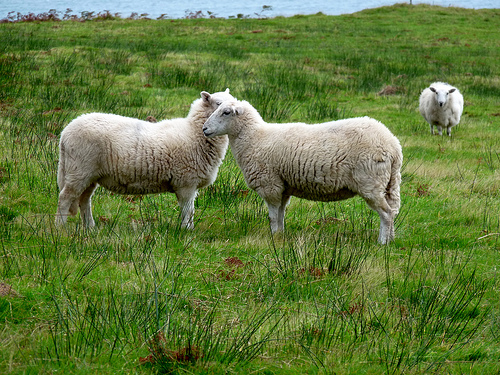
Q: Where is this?
A: This is at the field.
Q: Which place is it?
A: It is a field.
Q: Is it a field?
A: Yes, it is a field.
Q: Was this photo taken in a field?
A: Yes, it was taken in a field.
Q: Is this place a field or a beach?
A: It is a field.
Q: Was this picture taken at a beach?
A: No, the picture was taken in a field.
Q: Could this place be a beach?
A: No, it is a field.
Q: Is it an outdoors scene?
A: Yes, it is outdoors.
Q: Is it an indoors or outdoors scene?
A: It is outdoors.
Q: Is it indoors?
A: No, it is outdoors.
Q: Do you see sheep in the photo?
A: Yes, there is a sheep.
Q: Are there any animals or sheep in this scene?
A: Yes, there is a sheep.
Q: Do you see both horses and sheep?
A: No, there is a sheep but no horses.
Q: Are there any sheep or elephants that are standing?
A: Yes, the sheep is standing.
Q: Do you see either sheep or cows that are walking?
A: Yes, the sheep is walking.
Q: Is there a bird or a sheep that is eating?
A: Yes, the sheep is eating.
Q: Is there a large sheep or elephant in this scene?
A: Yes, there is a large sheep.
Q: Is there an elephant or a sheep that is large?
A: Yes, the sheep is large.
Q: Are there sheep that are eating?
A: Yes, there is a sheep that is eating.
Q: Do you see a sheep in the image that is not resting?
A: Yes, there is a sheep that is eating .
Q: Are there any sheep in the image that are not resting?
A: Yes, there is a sheep that is eating.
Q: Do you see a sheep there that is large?
A: Yes, there is a large sheep.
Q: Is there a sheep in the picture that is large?
A: Yes, there is a large sheep.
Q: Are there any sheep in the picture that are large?
A: Yes, there is a sheep that is large.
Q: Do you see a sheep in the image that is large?
A: Yes, there is a sheep that is large.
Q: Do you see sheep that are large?
A: Yes, there is a sheep that is large.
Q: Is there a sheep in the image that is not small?
A: Yes, there is a large sheep.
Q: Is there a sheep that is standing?
A: Yes, there is a sheep that is standing.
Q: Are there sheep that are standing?
A: Yes, there is a sheep that is standing.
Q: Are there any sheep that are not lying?
A: Yes, there is a sheep that is standing.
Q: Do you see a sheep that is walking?
A: Yes, there is a sheep that is walking.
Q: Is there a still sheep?
A: Yes, there is a still sheep.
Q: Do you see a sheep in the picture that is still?
A: Yes, there is a sheep that is still.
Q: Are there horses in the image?
A: No, there are no horses.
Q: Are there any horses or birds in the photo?
A: No, there are no horses or birds.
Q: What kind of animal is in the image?
A: The animal is a sheep.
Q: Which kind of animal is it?
A: The animal is a sheep.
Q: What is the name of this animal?
A: This is a sheep.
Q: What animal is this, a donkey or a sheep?
A: This is a sheep.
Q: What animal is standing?
A: The animal is a sheep.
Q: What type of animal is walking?
A: The animal is a sheep.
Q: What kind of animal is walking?
A: The animal is a sheep.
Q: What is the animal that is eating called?
A: The animal is a sheep.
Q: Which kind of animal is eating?
A: The animal is a sheep.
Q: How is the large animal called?
A: The animal is a sheep.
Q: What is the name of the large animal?
A: The animal is a sheep.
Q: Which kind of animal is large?
A: The animal is a sheep.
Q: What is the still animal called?
A: The animal is a sheep.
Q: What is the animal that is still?
A: The animal is a sheep.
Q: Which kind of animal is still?
A: The animal is a sheep.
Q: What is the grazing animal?
A: The animal is a sheep.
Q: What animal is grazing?
A: The animal is a sheep.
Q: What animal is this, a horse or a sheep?
A: This is a sheep.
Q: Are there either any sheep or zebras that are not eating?
A: No, there is a sheep but it is eating.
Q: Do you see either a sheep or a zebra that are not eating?
A: No, there is a sheep but it is eating.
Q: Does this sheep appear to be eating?
A: Yes, the sheep is eating.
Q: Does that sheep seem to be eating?
A: Yes, the sheep is eating.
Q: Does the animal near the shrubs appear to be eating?
A: Yes, the sheep is eating.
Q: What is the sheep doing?
A: The sheep is eating.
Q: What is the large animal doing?
A: The sheep is eating.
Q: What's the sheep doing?
A: The sheep is eating.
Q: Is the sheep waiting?
A: No, the sheep is eating.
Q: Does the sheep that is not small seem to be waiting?
A: No, the sheep is eating.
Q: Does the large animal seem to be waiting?
A: No, the sheep is eating.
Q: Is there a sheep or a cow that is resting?
A: No, there is a sheep but it is eating.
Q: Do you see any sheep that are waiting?
A: No, there is a sheep but it is eating.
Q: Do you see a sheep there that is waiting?
A: No, there is a sheep but it is eating.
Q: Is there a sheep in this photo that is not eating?
A: No, there is a sheep but it is eating.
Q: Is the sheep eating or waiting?
A: The sheep is eating.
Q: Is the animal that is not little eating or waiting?
A: The sheep is eating.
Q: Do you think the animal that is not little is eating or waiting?
A: The sheep is eating.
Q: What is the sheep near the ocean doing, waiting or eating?
A: The sheep is eating.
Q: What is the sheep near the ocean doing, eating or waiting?
A: The sheep is eating.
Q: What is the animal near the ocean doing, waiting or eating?
A: The sheep is eating.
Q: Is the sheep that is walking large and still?
A: Yes, the sheep is large and still.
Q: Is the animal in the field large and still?
A: Yes, the sheep is large and still.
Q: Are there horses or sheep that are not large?
A: No, there is a sheep but it is large.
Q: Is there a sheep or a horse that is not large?
A: No, there is a sheep but it is large.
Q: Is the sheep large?
A: Yes, the sheep is large.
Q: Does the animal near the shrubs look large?
A: Yes, the sheep is large.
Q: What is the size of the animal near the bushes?
A: The sheep is large.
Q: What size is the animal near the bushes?
A: The sheep is large.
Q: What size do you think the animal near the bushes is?
A: The sheep is large.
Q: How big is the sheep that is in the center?
A: The sheep is large.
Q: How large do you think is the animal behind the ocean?
A: The sheep is large.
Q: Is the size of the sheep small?
A: No, the sheep is large.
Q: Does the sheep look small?
A: No, the sheep is large.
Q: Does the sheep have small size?
A: No, the sheep is large.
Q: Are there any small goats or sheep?
A: No, there is a sheep but it is large.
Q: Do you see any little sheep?
A: No, there is a sheep but it is large.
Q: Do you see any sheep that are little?
A: No, there is a sheep but it is large.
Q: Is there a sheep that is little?
A: No, there is a sheep but it is large.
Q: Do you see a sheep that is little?
A: No, there is a sheep but it is large.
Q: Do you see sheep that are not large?
A: No, there is a sheep but it is large.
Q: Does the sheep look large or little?
A: The sheep is large.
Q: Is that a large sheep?
A: Yes, that is a large sheep.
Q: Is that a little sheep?
A: No, that is a large sheep.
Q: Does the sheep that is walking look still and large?
A: Yes, the sheep is still and large.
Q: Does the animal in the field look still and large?
A: Yes, the sheep is still and large.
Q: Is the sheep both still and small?
A: No, the sheep is still but large.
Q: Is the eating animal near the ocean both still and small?
A: No, the sheep is still but large.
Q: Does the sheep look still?
A: Yes, the sheep is still.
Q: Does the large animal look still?
A: Yes, the sheep is still.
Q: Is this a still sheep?
A: Yes, this is a still sheep.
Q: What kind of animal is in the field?
A: The animal is a sheep.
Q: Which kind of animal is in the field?
A: The animal is a sheep.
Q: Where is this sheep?
A: The sheep is in the field.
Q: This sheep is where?
A: The sheep is in the field.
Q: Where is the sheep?
A: The sheep is in the field.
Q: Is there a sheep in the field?
A: Yes, there is a sheep in the field.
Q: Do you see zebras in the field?
A: No, there is a sheep in the field.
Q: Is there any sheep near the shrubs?
A: Yes, there is a sheep near the shrubs.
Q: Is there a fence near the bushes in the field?
A: No, there is a sheep near the shrubs.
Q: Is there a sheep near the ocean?
A: Yes, there is a sheep near the ocean.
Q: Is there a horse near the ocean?
A: No, there is a sheep near the ocean.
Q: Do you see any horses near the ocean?
A: No, there is a sheep near the ocean.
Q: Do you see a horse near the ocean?
A: No, there is a sheep near the ocean.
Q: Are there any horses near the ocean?
A: No, there is a sheep near the ocean.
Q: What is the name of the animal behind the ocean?
A: The animal is a sheep.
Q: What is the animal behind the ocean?
A: The animal is a sheep.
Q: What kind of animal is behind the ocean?
A: The animal is a sheep.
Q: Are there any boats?
A: No, there are no boats.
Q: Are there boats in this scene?
A: No, there are no boats.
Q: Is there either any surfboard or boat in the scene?
A: No, there are no boats or surfboards.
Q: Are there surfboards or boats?
A: No, there are no boats or surfboards.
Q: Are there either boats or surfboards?
A: No, there are no boats or surfboards.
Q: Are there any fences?
A: No, there are no fences.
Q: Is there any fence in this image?
A: No, there are no fences.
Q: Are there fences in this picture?
A: No, there are no fences.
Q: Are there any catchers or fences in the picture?
A: No, there are no fences or catchers.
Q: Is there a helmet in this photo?
A: No, there are no helmets.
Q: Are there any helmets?
A: No, there are no helmets.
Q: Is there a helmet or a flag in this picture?
A: No, there are no helmets or flags.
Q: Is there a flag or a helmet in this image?
A: No, there are no helmets or flags.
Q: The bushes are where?
A: The bushes are in the field.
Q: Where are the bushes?
A: The bushes are in the field.